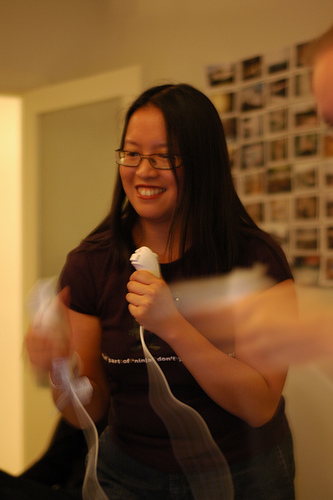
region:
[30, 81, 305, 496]
woman playing wii game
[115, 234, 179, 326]
holding wii controller in hand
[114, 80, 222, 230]
woman wearing glasses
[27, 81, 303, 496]
woman wearing glasses playing wii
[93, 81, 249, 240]
woman smiling wearing glasses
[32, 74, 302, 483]
woman wearing black shirt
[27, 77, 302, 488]
woman wearing glasses holding wii controllers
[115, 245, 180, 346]
wii controller in hand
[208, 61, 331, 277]
pictures on wall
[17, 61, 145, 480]
doorway behind woman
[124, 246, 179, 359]
Wii controllers for a video game system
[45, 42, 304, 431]
girl playing a video game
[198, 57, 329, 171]
photographs hanging on a wall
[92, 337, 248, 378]
white lettering on a black tshirt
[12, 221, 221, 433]
girl holding video game controllers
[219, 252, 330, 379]
hand moving with a game controller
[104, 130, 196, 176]
girl wearing wire framed glasses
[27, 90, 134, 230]
an open doorway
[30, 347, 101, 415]
wrist wrap for a Wii controller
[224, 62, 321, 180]
pictures taped to a wall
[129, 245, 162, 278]
handheld video game controller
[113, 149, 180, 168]
pair of corrective eyeglasses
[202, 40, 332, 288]
batch of small photos on wall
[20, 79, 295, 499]
dark haired girl playing game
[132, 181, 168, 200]
smiling mouth showing teeth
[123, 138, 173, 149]
girl's dark colored eyebrows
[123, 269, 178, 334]
girl's left hand holding gaming controller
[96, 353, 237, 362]
white text on front of graphic t-shirt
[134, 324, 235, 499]
white wire strap of left game controller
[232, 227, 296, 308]
girl's left shoulder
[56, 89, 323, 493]
a girl holding Wii controlers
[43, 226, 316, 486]
a black shirt with white writing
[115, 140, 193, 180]
glasses worn on face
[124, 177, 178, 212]
the girl is smiling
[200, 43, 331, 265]
a bunch of pictures on the wall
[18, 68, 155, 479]
a white door with a window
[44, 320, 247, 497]
a white cord attached to controlers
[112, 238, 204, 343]
a white controler in hand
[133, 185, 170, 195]
white straight teeth of woman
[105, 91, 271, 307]
long black hair on head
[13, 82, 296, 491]
girl having fun playing a video game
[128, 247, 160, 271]
game controller being held stable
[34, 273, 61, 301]
video game controller in motion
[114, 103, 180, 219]
smiling face of the video game player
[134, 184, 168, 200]
smiling mouth of video game player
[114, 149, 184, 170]
dark rimmed glasses of video game player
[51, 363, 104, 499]
video game controller cable in motion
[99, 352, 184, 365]
visible part of the slogan on her t-shirt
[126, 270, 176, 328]
hand holding the video game controller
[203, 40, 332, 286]
picture collection on the back wall